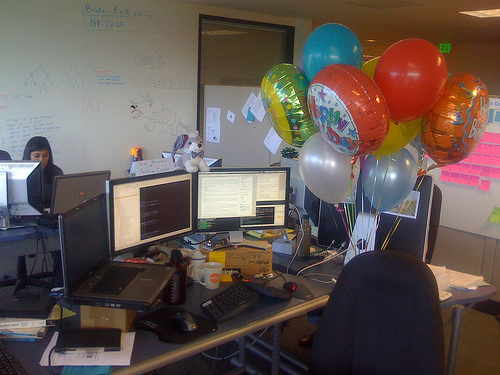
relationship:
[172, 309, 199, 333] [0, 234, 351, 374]
mouse on desk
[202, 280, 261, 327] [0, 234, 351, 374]
keyboard on desk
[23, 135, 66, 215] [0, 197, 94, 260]
woman at desk